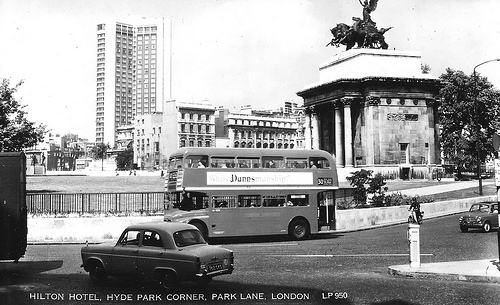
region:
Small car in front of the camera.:
[76, 217, 237, 286]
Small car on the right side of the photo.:
[459, 201, 499, 232]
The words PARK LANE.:
[208, 291, 265, 302]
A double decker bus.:
[162, 148, 338, 238]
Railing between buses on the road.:
[24, 189, 171, 216]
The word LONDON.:
[268, 289, 310, 302]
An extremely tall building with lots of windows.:
[92, 12, 173, 158]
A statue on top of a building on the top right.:
[325, 0, 397, 54]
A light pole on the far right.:
[470, 53, 498, 195]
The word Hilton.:
[25, 289, 65, 302]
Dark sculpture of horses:
[328, 20, 362, 47]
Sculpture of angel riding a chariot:
[356, 0, 387, 24]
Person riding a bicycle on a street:
[405, 196, 426, 228]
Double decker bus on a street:
[154, 144, 345, 237]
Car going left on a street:
[75, 218, 240, 286]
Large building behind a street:
[93, 15, 169, 173]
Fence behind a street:
[25, 182, 184, 220]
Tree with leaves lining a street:
[431, 63, 498, 197]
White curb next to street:
[385, 251, 499, 288]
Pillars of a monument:
[332, 97, 353, 169]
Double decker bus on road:
[158, 148, 358, 247]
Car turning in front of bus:
[66, 215, 230, 297]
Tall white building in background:
[81, 13, 186, 152]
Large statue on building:
[325, 1, 399, 58]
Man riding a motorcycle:
[401, 196, 427, 228]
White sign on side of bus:
[200, 168, 320, 198]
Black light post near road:
[464, 45, 499, 195]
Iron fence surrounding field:
[38, 186, 156, 218]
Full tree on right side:
[426, 66, 498, 181]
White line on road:
[266, 247, 436, 276]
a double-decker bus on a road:
[160, 135, 360, 241]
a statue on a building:
[325, 5, 396, 50]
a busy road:
[1, 196, 496, 301]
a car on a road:
[77, 212, 240, 287]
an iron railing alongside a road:
[25, 185, 171, 215]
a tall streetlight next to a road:
[465, 50, 495, 202]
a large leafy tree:
[438, 67, 496, 176]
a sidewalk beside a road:
[405, 244, 496, 291]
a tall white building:
[90, 9, 176, 178]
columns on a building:
[302, 96, 372, 191]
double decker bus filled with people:
[160, 145, 347, 243]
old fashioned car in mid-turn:
[76, 206, 250, 289]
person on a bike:
[403, 194, 427, 226]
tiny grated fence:
[24, 191, 166, 211]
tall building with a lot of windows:
[86, 5, 176, 159]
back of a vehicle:
[2, 149, 32, 266]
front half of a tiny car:
[458, 194, 498, 234]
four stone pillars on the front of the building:
[301, 103, 356, 168]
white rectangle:
[203, 168, 320, 188]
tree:
[437, 76, 495, 179]